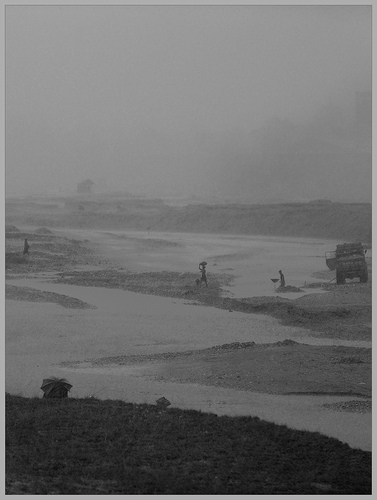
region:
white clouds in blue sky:
[33, 57, 59, 90]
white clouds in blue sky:
[161, 79, 211, 135]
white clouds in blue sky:
[225, 14, 242, 47]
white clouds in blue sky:
[30, 54, 81, 121]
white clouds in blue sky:
[95, 172, 130, 196]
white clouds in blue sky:
[68, 3, 124, 83]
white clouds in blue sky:
[150, 62, 201, 96]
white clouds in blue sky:
[79, 114, 118, 158]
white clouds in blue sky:
[203, 76, 263, 137]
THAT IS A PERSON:
[20, 235, 36, 260]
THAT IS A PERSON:
[188, 255, 210, 298]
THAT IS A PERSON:
[276, 264, 290, 297]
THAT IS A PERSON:
[43, 370, 73, 422]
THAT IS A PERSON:
[151, 392, 176, 411]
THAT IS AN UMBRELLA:
[46, 376, 79, 393]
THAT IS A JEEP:
[323, 237, 365, 282]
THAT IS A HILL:
[228, 208, 338, 230]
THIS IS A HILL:
[101, 435, 232, 461]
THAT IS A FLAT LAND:
[95, 289, 154, 335]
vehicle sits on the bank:
[324, 239, 369, 283]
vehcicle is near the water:
[321, 239, 369, 284]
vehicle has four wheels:
[325, 239, 369, 284]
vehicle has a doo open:
[324, 237, 371, 282]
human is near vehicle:
[269, 267, 287, 288]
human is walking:
[195, 259, 210, 283]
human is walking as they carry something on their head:
[196, 260, 212, 284]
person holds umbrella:
[40, 373, 73, 400]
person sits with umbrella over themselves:
[40, 374, 72, 400]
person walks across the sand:
[22, 236, 32, 255]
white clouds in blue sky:
[16, 29, 52, 66]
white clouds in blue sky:
[211, 208, 233, 225]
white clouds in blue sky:
[238, 92, 290, 176]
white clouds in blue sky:
[316, 137, 341, 163]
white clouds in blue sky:
[133, 95, 157, 132]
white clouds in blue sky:
[14, 51, 81, 93]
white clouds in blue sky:
[161, 20, 193, 65]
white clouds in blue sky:
[121, 111, 152, 140]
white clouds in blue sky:
[190, 24, 230, 83]